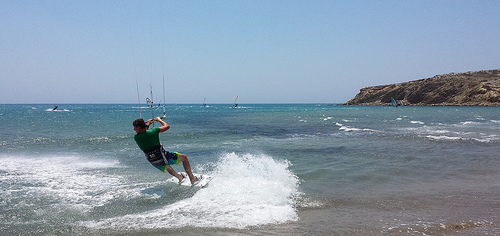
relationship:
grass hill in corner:
[342, 68, 500, 108] [342, 67, 497, 229]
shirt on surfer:
[130, 124, 169, 163] [117, 104, 189, 189]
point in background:
[344, 68, 499, 103] [1, 57, 495, 127]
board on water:
[170, 171, 214, 189] [193, 167, 276, 207]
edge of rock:
[344, 86, 365, 103] [347, 68, 497, 105]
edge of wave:
[272, 152, 302, 222] [96, 148, 308, 233]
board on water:
[159, 169, 218, 191] [205, 125, 451, 196]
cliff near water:
[348, 64, 499, 106] [6, 105, 489, 232]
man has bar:
[132, 116, 199, 185] [145, 114, 165, 122]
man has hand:
[132, 116, 199, 185] [152, 110, 162, 122]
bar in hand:
[145, 114, 165, 122] [152, 110, 162, 122]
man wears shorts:
[132, 116, 199, 185] [149, 149, 180, 171]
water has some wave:
[6, 105, 489, 232] [82, 145, 306, 231]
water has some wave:
[6, 105, 489, 232] [2, 147, 160, 215]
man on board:
[125, 110, 198, 187] [171, 167, 211, 188]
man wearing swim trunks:
[132, 116, 199, 185] [145, 149, 178, 168]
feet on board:
[176, 167, 202, 184] [165, 165, 215, 190]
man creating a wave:
[132, 116, 199, 185] [96, 148, 308, 233]